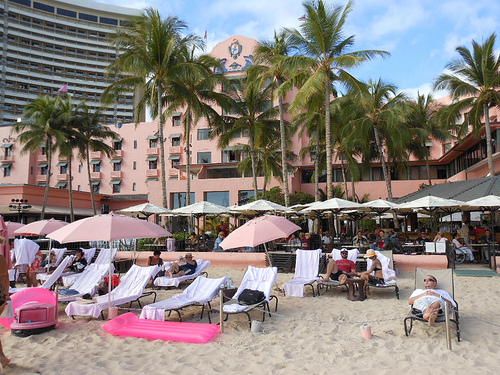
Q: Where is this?
A: This is at the beach.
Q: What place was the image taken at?
A: It was taken at the beach.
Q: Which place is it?
A: It is a beach.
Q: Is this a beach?
A: Yes, it is a beach.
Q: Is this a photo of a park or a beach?
A: It is showing a beach.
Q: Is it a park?
A: No, it is a beach.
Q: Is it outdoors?
A: Yes, it is outdoors.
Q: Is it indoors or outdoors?
A: It is outdoors.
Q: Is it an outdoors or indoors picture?
A: It is outdoors.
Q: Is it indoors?
A: No, it is outdoors.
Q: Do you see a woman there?
A: Yes, there is a woman.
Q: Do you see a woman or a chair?
A: Yes, there is a woman.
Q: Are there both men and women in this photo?
A: Yes, there are both a woman and a man.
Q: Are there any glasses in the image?
A: No, there are no glasses.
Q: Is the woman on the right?
A: Yes, the woman is on the right of the image.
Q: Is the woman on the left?
A: No, the woman is on the right of the image.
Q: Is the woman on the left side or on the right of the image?
A: The woman is on the right of the image.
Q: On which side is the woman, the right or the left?
A: The woman is on the right of the image.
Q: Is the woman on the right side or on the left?
A: The woman is on the right of the image.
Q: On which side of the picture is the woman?
A: The woman is on the right of the image.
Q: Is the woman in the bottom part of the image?
A: Yes, the woman is in the bottom of the image.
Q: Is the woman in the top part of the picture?
A: No, the woman is in the bottom of the image.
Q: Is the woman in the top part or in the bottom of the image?
A: The woman is in the bottom of the image.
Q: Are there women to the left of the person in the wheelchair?
A: Yes, there is a woman to the left of the person.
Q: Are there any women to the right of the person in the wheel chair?
A: No, the woman is to the left of the person.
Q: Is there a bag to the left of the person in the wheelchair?
A: No, there is a woman to the left of the person.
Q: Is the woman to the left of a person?
A: Yes, the woman is to the left of a person.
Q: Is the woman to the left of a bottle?
A: No, the woman is to the left of a person.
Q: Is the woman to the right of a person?
A: No, the woman is to the left of a person.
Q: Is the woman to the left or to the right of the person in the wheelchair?
A: The woman is to the left of the person.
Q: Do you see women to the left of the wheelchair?
A: Yes, there is a woman to the left of the wheelchair.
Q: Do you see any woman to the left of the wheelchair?
A: Yes, there is a woman to the left of the wheelchair.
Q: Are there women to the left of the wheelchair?
A: Yes, there is a woman to the left of the wheelchair.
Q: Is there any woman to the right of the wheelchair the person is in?
A: No, the woman is to the left of the wheelchair.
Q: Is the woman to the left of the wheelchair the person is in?
A: Yes, the woman is to the left of the wheel chair.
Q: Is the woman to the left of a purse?
A: No, the woman is to the left of the wheel chair.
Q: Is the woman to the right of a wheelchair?
A: No, the woman is to the left of a wheelchair.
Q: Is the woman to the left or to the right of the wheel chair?
A: The woman is to the left of the wheel chair.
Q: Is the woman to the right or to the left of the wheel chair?
A: The woman is to the left of the wheel chair.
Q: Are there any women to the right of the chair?
A: Yes, there is a woman to the right of the chair.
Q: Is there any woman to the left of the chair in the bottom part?
A: No, the woman is to the right of the chair.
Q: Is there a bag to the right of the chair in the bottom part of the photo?
A: No, there is a woman to the right of the chair.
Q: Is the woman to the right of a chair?
A: Yes, the woman is to the right of a chair.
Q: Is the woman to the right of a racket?
A: No, the woman is to the right of a chair.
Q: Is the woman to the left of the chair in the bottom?
A: No, the woman is to the right of the chair.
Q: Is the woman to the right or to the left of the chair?
A: The woman is to the right of the chair.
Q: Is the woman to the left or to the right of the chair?
A: The woman is to the right of the chair.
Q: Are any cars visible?
A: No, there are no cars.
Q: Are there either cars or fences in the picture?
A: No, there are no cars or fences.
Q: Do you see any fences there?
A: No, there are no fences.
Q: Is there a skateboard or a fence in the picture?
A: No, there are no fences or skateboards.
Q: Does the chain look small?
A: Yes, the chain is small.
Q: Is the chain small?
A: Yes, the chain is small.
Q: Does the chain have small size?
A: Yes, the chain is small.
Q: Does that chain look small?
A: Yes, the chain is small.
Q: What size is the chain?
A: The chain is small.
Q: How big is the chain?
A: The chain is small.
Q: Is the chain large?
A: No, the chain is small.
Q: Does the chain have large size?
A: No, the chain is small.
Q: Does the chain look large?
A: No, the chain is small.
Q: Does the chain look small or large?
A: The chain is small.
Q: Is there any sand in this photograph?
A: Yes, there is sand.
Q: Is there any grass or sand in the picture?
A: Yes, there is sand.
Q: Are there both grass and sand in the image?
A: No, there is sand but no grass.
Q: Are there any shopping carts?
A: No, there are no shopping carts.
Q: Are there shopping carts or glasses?
A: No, there are no shopping carts or glasses.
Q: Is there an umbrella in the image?
A: Yes, there are umbrellas.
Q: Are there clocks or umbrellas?
A: Yes, there are umbrellas.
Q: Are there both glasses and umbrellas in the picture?
A: No, there are umbrellas but no glasses.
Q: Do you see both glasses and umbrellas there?
A: No, there are umbrellas but no glasses.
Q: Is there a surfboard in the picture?
A: No, there are no surfboards.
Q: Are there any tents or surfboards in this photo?
A: No, there are no surfboards or tents.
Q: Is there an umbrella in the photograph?
A: Yes, there are umbrellas.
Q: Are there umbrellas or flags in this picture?
A: Yes, there are umbrellas.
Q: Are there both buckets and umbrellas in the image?
A: No, there are umbrellas but no buckets.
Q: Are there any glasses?
A: No, there are no glasses.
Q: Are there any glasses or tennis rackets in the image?
A: No, there are no glasses or tennis rackets.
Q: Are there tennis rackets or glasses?
A: No, there are no glasses or tennis rackets.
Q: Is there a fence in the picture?
A: No, there are no fences.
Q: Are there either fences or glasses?
A: No, there are no fences or glasses.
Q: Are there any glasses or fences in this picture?
A: No, there are no fences or glasses.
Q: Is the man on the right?
A: Yes, the man is on the right of the image.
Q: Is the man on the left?
A: No, the man is on the right of the image.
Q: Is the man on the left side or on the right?
A: The man is on the right of the image.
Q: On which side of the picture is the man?
A: The man is on the right of the image.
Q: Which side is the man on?
A: The man is on the right of the image.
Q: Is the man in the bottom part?
A: Yes, the man is in the bottom of the image.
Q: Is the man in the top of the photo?
A: No, the man is in the bottom of the image.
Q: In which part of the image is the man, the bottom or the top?
A: The man is in the bottom of the image.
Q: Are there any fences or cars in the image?
A: No, there are no cars or fences.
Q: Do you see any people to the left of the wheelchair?
A: Yes, there are people to the left of the wheelchair.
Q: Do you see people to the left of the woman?
A: Yes, there are people to the left of the woman.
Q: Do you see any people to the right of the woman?
A: No, the people are to the left of the woman.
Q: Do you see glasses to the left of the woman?
A: No, there are people to the left of the woman.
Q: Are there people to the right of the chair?
A: Yes, there are people to the right of the chair.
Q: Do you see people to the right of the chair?
A: Yes, there are people to the right of the chair.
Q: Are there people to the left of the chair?
A: No, the people are to the right of the chair.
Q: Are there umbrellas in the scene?
A: Yes, there is an umbrella.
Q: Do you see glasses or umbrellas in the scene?
A: Yes, there is an umbrella.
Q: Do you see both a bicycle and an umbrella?
A: No, there is an umbrella but no bicycles.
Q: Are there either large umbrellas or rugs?
A: Yes, there is a large umbrella.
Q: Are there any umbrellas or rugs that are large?
A: Yes, the umbrella is large.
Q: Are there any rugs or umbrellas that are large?
A: Yes, the umbrella is large.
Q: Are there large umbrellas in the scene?
A: Yes, there is a large umbrella.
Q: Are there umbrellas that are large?
A: Yes, there is an umbrella that is large.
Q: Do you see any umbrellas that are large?
A: Yes, there is an umbrella that is large.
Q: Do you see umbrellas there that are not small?
A: Yes, there is a large umbrella.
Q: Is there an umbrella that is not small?
A: Yes, there is a large umbrella.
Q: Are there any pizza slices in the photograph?
A: No, there are no pizza slices.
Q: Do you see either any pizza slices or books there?
A: No, there are no pizza slices or books.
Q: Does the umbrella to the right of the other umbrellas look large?
A: Yes, the umbrella is large.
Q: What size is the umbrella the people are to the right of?
A: The umbrella is large.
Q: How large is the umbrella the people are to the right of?
A: The umbrella is large.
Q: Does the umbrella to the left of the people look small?
A: No, the umbrella is large.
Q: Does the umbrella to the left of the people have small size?
A: No, the umbrella is large.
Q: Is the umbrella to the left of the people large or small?
A: The umbrella is large.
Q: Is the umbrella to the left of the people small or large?
A: The umbrella is large.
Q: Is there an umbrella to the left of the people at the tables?
A: Yes, there is an umbrella to the left of the people.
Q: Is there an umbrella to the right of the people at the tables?
A: No, the umbrella is to the left of the people.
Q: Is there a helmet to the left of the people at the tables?
A: No, there is an umbrella to the left of the people.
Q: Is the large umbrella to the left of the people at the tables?
A: Yes, the umbrella is to the left of the people.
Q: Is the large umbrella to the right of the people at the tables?
A: No, the umbrella is to the left of the people.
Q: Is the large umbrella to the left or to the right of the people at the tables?
A: The umbrella is to the left of the people.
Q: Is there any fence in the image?
A: No, there are no fences.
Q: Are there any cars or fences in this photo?
A: No, there are no fences or cars.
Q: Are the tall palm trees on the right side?
A: Yes, the palm trees are on the right of the image.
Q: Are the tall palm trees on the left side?
A: No, the palm trees are on the right of the image.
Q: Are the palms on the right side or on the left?
A: The palms are on the right of the image.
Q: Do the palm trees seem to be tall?
A: Yes, the palm trees are tall.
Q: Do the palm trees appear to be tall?
A: Yes, the palm trees are tall.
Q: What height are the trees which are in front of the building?
A: The palm trees are tall.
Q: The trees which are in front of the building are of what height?
A: The palm trees are tall.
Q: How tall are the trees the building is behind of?
A: The palm trees are tall.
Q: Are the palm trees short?
A: No, the palm trees are tall.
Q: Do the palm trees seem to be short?
A: No, the palm trees are tall.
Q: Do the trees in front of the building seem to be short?
A: No, the palm trees are tall.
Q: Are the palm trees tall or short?
A: The palm trees are tall.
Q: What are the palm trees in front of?
A: The palm trees are in front of the building.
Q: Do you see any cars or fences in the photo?
A: No, there are no fences or cars.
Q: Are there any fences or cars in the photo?
A: No, there are no fences or cars.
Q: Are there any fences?
A: No, there are no fences.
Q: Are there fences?
A: No, there are no fences.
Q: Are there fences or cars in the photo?
A: No, there are no fences or cars.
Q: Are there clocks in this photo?
A: No, there are no clocks.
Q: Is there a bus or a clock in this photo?
A: No, there are no clocks or buses.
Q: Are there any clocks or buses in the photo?
A: No, there are no clocks or buses.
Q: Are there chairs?
A: Yes, there is a chair.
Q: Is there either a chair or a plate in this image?
A: Yes, there is a chair.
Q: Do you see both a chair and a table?
A: Yes, there are both a chair and a table.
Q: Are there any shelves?
A: No, there are no shelves.